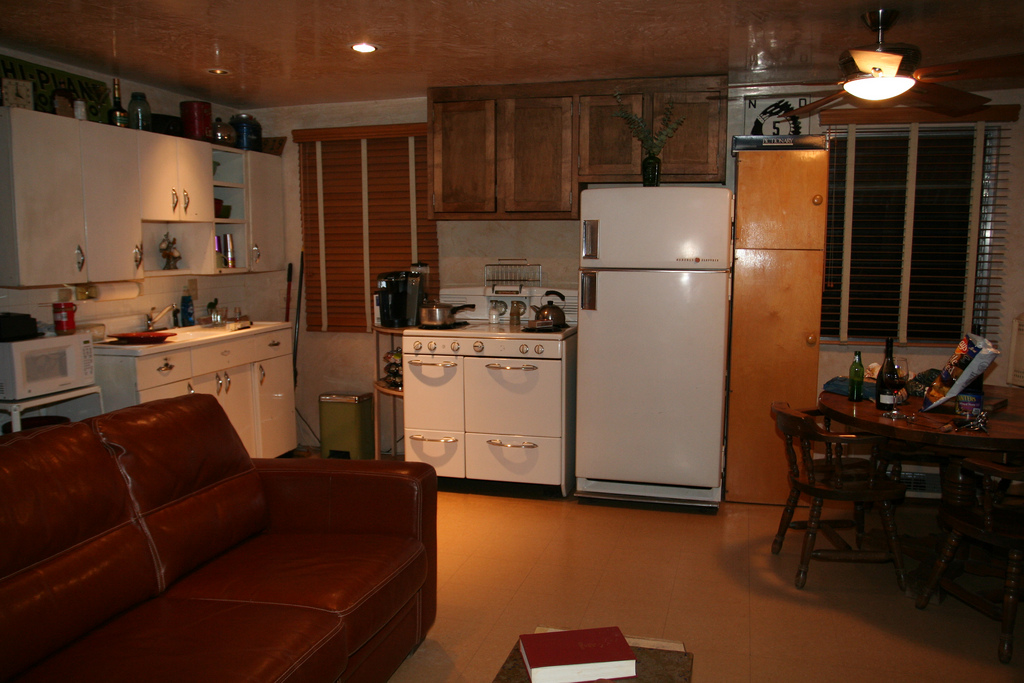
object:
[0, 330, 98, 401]
microwave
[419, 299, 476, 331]
pot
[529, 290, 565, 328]
kettle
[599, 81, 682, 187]
plant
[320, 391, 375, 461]
bin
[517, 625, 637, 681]
book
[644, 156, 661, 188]
vase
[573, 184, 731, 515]
fridge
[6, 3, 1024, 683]
kitche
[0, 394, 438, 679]
couch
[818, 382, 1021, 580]
table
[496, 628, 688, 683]
table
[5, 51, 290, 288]
cabinet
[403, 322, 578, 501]
stove